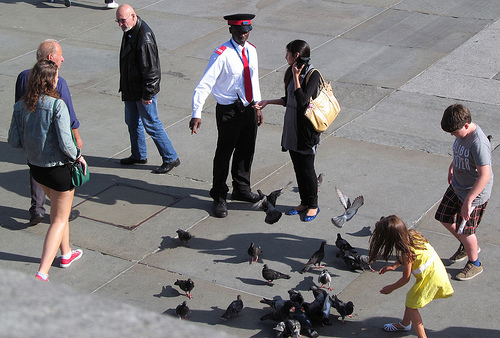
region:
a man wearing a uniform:
[187, 13, 263, 215]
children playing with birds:
[369, 105, 494, 337]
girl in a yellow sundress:
[369, 217, 453, 337]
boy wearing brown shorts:
[437, 107, 493, 279]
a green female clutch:
[68, 158, 90, 188]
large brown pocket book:
[304, 77, 339, 133]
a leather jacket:
[119, 25, 160, 98]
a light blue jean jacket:
[11, 95, 79, 162]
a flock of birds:
[176, 185, 372, 337]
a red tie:
[237, 48, 253, 102]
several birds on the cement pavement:
[171, 212, 369, 333]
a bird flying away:
[322, 182, 369, 230]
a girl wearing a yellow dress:
[364, 210, 457, 336]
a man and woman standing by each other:
[187, 9, 340, 222]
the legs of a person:
[38, 192, 88, 277]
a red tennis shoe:
[56, 245, 88, 270]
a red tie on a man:
[238, 46, 259, 101]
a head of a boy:
[434, 100, 477, 140]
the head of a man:
[114, 0, 143, 34]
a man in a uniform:
[186, 8, 268, 213]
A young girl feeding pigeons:
[351, 212, 461, 332]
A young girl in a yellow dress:
[355, 199, 472, 336]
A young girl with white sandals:
[360, 205, 455, 335]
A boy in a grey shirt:
[405, 95, 495, 285]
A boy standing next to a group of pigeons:
[430, 90, 490, 285]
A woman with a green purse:
[5, 45, 85, 285]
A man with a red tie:
[180, 5, 280, 215]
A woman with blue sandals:
[255, 35, 355, 215]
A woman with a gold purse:
[255, 30, 350, 220]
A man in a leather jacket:
[100, 1, 185, 172]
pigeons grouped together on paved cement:
[172, 187, 372, 337]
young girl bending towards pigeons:
[306, 212, 454, 337]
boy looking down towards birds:
[332, 103, 492, 279]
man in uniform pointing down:
[188, 12, 260, 217]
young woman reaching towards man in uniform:
[188, 10, 340, 222]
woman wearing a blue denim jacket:
[6, 94, 80, 166]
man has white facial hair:
[118, 20, 131, 31]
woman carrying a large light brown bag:
[300, 66, 340, 133]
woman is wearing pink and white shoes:
[36, 247, 82, 282]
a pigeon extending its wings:
[326, 183, 365, 231]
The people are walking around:
[26, 8, 479, 318]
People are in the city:
[11, 8, 486, 333]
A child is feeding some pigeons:
[23, 5, 488, 332]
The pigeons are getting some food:
[25, 11, 480, 331]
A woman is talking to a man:
[176, 5, 357, 222]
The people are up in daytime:
[11, 8, 496, 323]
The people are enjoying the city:
[5, 12, 495, 312]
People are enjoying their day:
[11, 12, 488, 305]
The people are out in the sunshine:
[5, 16, 492, 321]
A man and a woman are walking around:
[0, 35, 103, 292]